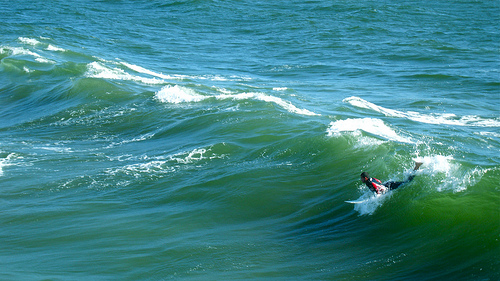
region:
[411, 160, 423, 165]
The foot of the surfer.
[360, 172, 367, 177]
The short black hair of the surfer.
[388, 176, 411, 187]
The pants of the wet suit.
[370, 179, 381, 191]
The shirt of the wet suit.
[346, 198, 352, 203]
The tip of the surfboard.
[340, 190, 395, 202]
The surfboard the surfer is laying on.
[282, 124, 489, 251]
The wave the surfer is riding.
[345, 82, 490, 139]
The wave behind the surfer.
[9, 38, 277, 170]
The waves on the left.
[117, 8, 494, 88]
The water in the distance.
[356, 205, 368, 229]
part of a splash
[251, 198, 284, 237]
part of a water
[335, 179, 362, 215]
part of a board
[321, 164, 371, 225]
part of a board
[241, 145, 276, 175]
part of a wave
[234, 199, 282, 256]
part of a water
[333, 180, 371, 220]
part of a water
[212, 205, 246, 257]
part of a water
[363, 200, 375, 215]
part of a splash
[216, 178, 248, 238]
part of a water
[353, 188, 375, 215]
part of a splah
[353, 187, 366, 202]
part of a board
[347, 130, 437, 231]
a male surfer getting ready to ride a wave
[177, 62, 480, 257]
male surfer getting ready to ride a wave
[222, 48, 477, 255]
surfer getting ready to ride a wave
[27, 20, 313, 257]
beautiful green and blue ocean water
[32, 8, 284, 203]
green and blue ocean water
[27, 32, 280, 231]
beautiful green and blue ocean water with waves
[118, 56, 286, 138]
beautiful green and blue ocean water with foam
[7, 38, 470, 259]
surfer riding a wave on his surfboard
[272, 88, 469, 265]
surfer riding a wave on his white boar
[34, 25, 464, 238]
surfer riding a wave with his wetsuit on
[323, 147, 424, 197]
person is riding wave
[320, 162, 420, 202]
person on white surfboard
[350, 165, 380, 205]
person has dark hair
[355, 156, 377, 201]
person has red top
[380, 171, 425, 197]
person has dark pants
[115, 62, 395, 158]
white caps on waves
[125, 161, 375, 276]
water is blue and green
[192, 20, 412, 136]
choppy waves on water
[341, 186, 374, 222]
person's surfboard is white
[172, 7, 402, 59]
calm water behind wave